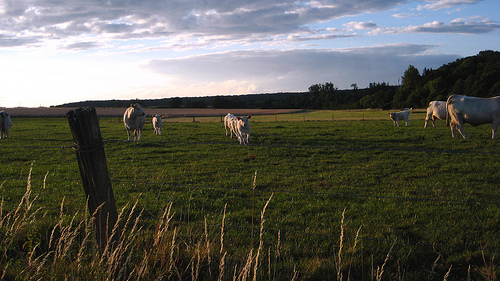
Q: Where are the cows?
A: In field.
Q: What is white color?
A: Cows.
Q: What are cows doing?
A: Grazing.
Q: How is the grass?
A: Tall.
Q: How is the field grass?
A: Cut.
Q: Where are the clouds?
A: Sky.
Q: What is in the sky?
A: Clouds.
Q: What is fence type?
A: Hedge post.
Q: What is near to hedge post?
A: Weeds.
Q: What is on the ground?
A: Cow.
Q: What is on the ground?
A: Field.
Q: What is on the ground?
A: Grass.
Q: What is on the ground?
A: Grass.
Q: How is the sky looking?
A: Cloudy.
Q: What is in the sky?
A: Clouds.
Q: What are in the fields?
A: Cows.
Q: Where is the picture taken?
A: Field.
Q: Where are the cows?
A: In the field.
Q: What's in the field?
A: Cows.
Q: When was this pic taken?
A: During the day.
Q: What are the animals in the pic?
A: Cows.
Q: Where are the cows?
A: In a big field.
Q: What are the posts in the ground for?
A: Fencing.